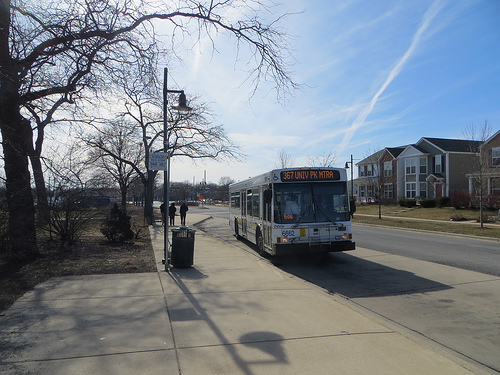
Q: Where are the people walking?
A: On the sidewalk.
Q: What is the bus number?
A: 367.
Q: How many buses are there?
A: 1.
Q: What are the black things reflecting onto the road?
A: Shadows.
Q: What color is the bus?
A: White.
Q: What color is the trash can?
A: Black.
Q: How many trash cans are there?
A: One.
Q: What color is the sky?
A: Blue.